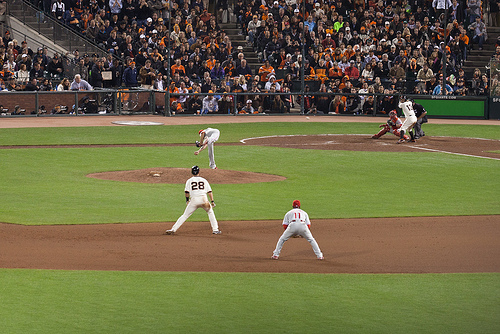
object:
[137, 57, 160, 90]
fans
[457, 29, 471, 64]
bleachers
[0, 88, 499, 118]
fence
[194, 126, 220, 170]
pitcher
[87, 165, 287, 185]
mound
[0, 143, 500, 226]
diamond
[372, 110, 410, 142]
catcher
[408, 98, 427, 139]
umpire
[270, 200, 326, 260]
man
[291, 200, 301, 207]
cap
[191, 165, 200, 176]
helmet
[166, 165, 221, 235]
man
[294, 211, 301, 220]
number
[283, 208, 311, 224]
shirt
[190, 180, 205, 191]
number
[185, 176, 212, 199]
shirt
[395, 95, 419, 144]
players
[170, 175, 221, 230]
uniform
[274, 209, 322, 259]
uniform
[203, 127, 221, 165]
uniform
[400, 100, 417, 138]
uniform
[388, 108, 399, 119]
helmet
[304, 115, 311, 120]
ball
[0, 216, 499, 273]
dirt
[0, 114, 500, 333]
field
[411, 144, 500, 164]
line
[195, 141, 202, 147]
glove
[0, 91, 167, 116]
dugout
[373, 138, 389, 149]
plate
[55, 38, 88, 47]
stairs